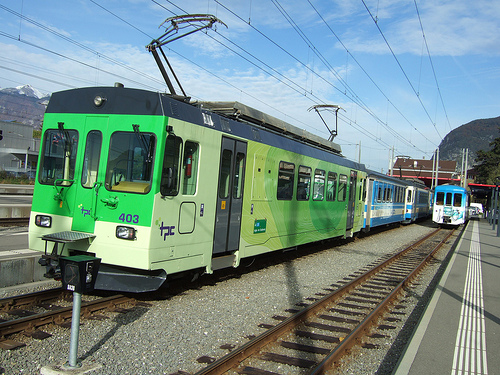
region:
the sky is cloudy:
[166, 31, 477, 251]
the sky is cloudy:
[165, 20, 343, 132]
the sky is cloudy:
[213, 38, 317, 163]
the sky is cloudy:
[260, 41, 437, 171]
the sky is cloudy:
[197, 41, 359, 78]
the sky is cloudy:
[235, 11, 323, 61]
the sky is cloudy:
[237, 57, 342, 87]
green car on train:
[31, 85, 366, 294]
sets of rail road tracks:
[1, 224, 461, 374]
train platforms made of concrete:
[1, 181, 498, 373]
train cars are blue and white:
[362, 168, 467, 230]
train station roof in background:
[386, 151, 493, 193]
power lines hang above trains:
[0, 0, 462, 177]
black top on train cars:
[46, 81, 431, 191]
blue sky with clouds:
[1, 1, 498, 173]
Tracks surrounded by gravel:
[0, 226, 466, 374]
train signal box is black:
[44, 255, 100, 374]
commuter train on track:
[31, 96, 387, 295]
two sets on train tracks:
[32, 280, 352, 361]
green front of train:
[32, 106, 172, 230]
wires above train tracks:
[255, 19, 405, 84]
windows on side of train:
[269, 168, 347, 200]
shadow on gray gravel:
[273, 251, 327, 311]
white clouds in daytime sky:
[272, 56, 358, 106]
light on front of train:
[104, 221, 134, 242]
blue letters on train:
[113, 206, 145, 228]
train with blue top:
[425, 173, 470, 223]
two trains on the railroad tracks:
[27, 84, 469, 294]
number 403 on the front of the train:
[117, 212, 139, 225]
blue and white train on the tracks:
[430, 181, 467, 228]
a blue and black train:
[25, 85, 365, 293]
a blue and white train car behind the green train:
[365, 172, 429, 232]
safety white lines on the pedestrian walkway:
[450, 220, 487, 373]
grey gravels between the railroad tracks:
[109, 319, 196, 359]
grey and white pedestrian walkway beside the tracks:
[395, 225, 498, 372]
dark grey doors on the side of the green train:
[212, 135, 246, 252]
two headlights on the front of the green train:
[33, 214, 135, 240]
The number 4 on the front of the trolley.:
[116, 210, 121, 220]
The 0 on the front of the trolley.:
[125, 206, 130, 217]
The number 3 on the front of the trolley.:
[135, 211, 140, 221]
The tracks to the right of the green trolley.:
[206, 220, 451, 360]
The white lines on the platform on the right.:
[442, 215, 482, 372]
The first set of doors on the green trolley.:
[215, 135, 245, 250]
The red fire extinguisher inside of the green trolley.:
[181, 145, 191, 176]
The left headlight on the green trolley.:
[32, 213, 54, 227]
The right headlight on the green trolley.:
[115, 222, 133, 242]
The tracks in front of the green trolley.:
[0, 284, 130, 329]